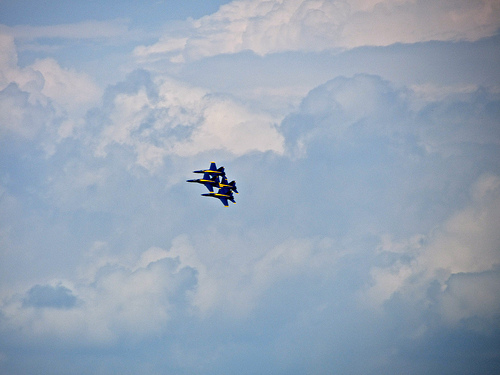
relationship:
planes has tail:
[174, 157, 247, 211] [230, 177, 239, 194]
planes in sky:
[174, 157, 247, 211] [58, 4, 405, 156]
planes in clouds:
[174, 157, 247, 211] [173, 6, 396, 116]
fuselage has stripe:
[213, 191, 236, 200] [211, 193, 233, 198]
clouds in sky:
[173, 6, 396, 116] [58, 4, 405, 156]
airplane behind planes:
[185, 172, 219, 193] [192, 161, 226, 179]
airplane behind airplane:
[200, 186, 237, 207] [215, 172, 238, 193]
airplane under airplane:
[182, 174, 220, 188] [185, 153, 225, 182]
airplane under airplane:
[194, 186, 235, 204] [207, 175, 240, 201]